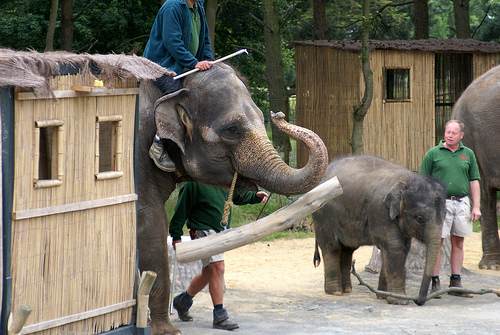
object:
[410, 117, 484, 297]
man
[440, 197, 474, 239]
shorts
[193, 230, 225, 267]
shorts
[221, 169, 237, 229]
rope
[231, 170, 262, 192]
mouth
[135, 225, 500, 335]
ground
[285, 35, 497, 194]
building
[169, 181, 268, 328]
man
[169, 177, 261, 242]
shirt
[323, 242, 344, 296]
limb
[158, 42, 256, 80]
stick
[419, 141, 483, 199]
shirt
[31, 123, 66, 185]
window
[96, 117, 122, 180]
window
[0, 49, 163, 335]
shack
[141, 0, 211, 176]
man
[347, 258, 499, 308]
stick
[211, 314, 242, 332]
shoes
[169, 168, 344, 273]
sticks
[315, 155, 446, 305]
baby elephant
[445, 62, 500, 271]
elephant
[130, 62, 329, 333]
elephant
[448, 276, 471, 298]
boots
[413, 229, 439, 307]
trunk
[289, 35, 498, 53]
roof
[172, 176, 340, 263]
log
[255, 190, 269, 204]
man's hand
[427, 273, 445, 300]
shoe